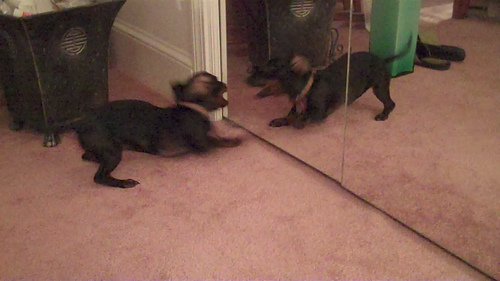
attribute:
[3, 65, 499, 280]
carpet — pink, patch, large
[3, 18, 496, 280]
floor — brown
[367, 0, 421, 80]
container — green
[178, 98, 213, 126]
collar — brown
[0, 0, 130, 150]
container — black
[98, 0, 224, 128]
wall — white, wood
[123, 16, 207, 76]
wall — white 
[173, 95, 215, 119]
collar — red, pink, dog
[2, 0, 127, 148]
can — metal, decorative, trash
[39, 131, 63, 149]
foot — black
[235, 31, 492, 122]
mirror — Big 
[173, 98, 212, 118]
collar — light brown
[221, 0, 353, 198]
door — glass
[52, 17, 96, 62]
circle — tan 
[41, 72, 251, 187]
dog — collar, Reflection 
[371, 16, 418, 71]
post — large square green  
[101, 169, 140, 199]
foot — dog's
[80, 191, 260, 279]
carpet — pink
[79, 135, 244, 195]
legs — short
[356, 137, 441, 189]
mirror — clear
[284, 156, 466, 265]
lines — straight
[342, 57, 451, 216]
lmirrors — bottom 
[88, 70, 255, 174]
dog — barking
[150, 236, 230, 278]
floor — pink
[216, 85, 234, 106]
mouth — open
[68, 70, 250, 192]
dog — black, reflection, dark, brown, barking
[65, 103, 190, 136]
coat — black, shiny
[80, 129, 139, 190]
leg — back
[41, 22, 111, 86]
drawer — brown  